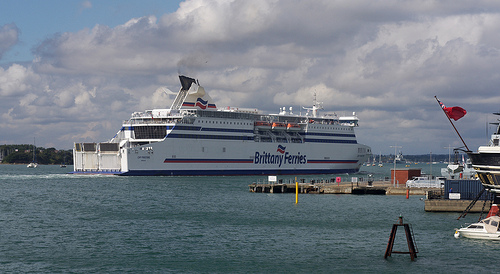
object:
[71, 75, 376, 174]
ship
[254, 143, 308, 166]
logo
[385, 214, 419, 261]
buoy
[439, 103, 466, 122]
flag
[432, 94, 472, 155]
pole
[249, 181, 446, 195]
pier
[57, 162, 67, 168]
boat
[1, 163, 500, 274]
water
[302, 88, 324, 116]
antennas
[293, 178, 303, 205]
pole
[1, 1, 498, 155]
sky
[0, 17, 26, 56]
clouds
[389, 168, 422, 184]
building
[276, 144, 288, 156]
flag image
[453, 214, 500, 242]
boat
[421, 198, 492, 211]
concrete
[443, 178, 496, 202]
container